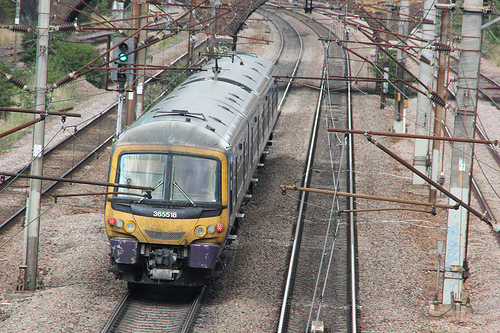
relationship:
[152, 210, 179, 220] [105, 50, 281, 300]
identification number on train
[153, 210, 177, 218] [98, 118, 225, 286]
identification number on train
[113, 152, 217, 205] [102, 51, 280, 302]
shield on passenger train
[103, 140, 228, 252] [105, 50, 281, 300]
yellow part of train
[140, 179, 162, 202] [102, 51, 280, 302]
wiper on front of passenger train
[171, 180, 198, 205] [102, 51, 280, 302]
wiper on front of passenger train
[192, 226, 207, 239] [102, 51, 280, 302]
head lights on front of passenger train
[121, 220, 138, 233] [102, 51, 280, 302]
head lights on front of passenger train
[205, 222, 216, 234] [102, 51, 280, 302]
head lights on front of passenger train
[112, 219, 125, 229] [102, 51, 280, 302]
head lights on front of passenger train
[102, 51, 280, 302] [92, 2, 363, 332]
passenger train on tracks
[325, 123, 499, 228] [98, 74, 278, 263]
poles above train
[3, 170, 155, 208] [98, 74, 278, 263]
poles above train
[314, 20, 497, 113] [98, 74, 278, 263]
poles above train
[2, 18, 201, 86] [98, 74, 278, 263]
poles above train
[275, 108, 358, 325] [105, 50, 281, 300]
tracks next to train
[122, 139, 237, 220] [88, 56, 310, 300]
windshield in front of a train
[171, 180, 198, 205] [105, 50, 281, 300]
wiper on a train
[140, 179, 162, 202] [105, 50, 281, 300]
wiper on a train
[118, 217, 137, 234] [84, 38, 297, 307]
headlight on front of train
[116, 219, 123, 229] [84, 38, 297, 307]
head lights on front of train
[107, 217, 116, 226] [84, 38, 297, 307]
headlight on front of train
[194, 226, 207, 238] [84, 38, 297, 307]
head lights on front of train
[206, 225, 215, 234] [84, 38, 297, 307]
head lights on front of train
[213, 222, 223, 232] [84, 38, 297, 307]
headlight on front of train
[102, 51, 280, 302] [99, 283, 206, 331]
passenger train on track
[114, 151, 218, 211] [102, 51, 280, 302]
front windshield of a passenger train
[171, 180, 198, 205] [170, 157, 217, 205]
wiper on a shield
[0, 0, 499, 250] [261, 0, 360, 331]
wires over a track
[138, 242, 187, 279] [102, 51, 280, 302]
coupling device of a passenger train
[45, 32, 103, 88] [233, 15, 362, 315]
shrubs near a train track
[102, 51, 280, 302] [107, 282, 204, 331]
passenger train on a railroad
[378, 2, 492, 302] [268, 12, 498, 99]
poles with power lines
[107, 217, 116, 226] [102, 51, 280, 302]
headlight in front of passenger train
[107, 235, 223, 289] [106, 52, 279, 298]
bumper of railroad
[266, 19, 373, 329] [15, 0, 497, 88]
railroad below powerlines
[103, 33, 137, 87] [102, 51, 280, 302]
light on left side of passenger train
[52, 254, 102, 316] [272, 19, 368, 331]
gravel on railroad